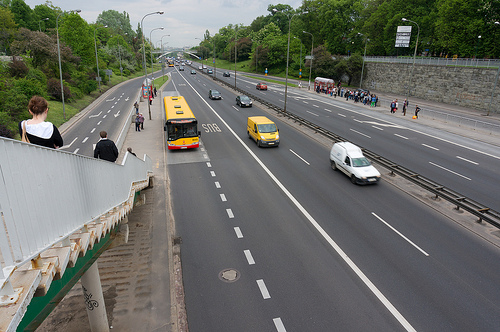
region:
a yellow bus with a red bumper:
[164, 95, 201, 153]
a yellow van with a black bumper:
[248, 115, 280, 145]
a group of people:
[311, 76, 424, 118]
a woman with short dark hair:
[15, 91, 65, 146]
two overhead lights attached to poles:
[135, 5, 160, 65]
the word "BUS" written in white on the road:
[200, 120, 220, 131]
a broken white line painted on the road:
[190, 146, 282, 326]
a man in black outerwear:
[90, 126, 117, 156]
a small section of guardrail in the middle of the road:
[402, 181, 498, 222]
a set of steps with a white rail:
[0, 133, 150, 330]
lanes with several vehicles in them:
[90, 63, 486, 320]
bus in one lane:
[151, 93, 203, 150]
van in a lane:
[237, 110, 281, 150]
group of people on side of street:
[306, 75, 426, 123]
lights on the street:
[138, 10, 179, 46]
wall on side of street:
[341, 60, 498, 106]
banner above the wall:
[385, 27, 414, 54]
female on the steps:
[9, 94, 61, 150]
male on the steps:
[87, 121, 115, 159]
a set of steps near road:
[3, 88, 158, 288]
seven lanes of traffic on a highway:
[163, 75, 374, 151]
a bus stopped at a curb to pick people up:
[146, 76, 196, 191]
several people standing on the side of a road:
[317, 77, 428, 131]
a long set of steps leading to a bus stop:
[21, 130, 180, 299]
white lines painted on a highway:
[138, 51, 466, 264]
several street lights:
[123, 10, 186, 152]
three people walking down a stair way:
[0, 99, 145, 194]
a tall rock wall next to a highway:
[349, 56, 485, 104]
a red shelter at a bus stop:
[312, 68, 337, 100]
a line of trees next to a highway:
[26, 53, 153, 126]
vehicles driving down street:
[202, 29, 438, 329]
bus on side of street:
[152, 75, 213, 193]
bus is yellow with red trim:
[146, 55, 216, 186]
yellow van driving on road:
[236, 103, 291, 156]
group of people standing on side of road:
[295, 55, 431, 135]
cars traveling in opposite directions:
[176, 20, 398, 192]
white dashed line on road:
[204, 154, 303, 330]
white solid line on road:
[233, 130, 427, 327]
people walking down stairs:
[10, 90, 177, 192]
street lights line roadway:
[117, 8, 193, 126]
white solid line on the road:
[262, 164, 417, 329]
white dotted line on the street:
[208, 168, 291, 330]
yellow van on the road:
[244, 111, 282, 149]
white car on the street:
[326, 136, 382, 187]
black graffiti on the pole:
[78, 281, 100, 316]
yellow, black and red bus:
[161, 92, 203, 155]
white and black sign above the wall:
[392, 21, 413, 49]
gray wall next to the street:
[355, 58, 499, 119]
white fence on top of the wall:
[361, 53, 498, 69]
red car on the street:
[254, 78, 269, 91]